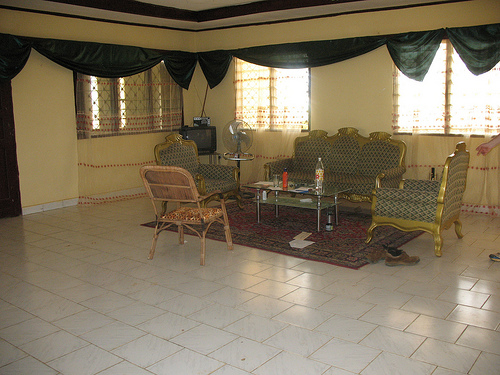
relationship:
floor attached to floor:
[0, 190, 500, 373] [0, 190, 500, 373]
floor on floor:
[0, 190, 500, 373] [0, 190, 500, 373]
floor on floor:
[0, 190, 500, 373] [7, 257, 184, 354]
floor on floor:
[0, 190, 500, 373] [137, 282, 388, 359]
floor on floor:
[0, 190, 500, 373] [298, 267, 337, 282]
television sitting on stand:
[179, 125, 217, 154] [201, 150, 223, 167]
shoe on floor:
[381, 242, 421, 269] [0, 190, 500, 373]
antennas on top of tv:
[186, 94, 216, 116] [173, 125, 218, 155]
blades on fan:
[234, 130, 249, 144] [221, 118, 257, 203]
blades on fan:
[224, 117, 239, 134] [221, 118, 257, 203]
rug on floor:
[143, 185, 430, 274] [0, 170, 498, 372]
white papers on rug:
[289, 231, 315, 248] [229, 210, 406, 266]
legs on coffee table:
[255, 201, 344, 231] [246, 170, 348, 237]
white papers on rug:
[288, 228, 314, 251] [141, 197, 428, 269]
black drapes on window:
[77, 38, 224, 103] [227, 63, 294, 138]